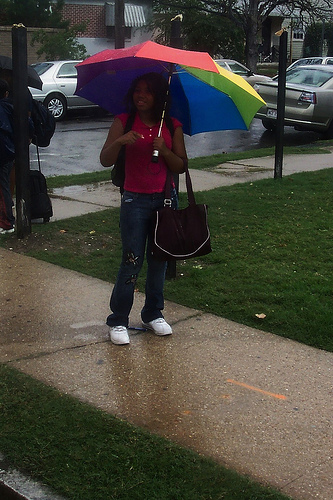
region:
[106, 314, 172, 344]
Girl wearing shoes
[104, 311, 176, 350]
Girl is wearing shoes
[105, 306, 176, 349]
Girl wearing white shoes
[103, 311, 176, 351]
Girl is wearing white shoes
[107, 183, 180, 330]
Girl wearing pants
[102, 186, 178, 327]
Girl is wearing pants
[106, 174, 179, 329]
Girl wearing blue pants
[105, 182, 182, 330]
Girl is wearing blue pants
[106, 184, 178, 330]
Girl wearing blue jeans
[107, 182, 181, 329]
Girl is wearing blue jeans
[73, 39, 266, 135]
a rainbow striped umbrella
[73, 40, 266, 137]
an open umbrella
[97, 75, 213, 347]
a young girl standing on sidewalk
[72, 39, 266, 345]
a young girl standing under umbrella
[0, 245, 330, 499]
a wet paved sidewalk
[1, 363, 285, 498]
a patch of green grass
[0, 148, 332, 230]
a paved wet sidewalk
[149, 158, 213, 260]
a large black bag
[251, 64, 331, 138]
a parked silver car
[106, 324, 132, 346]
a white shoe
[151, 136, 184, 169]
a hand holding a umbrella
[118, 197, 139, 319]
blue jeans worn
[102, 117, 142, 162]
the hand of a lady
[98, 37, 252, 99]
an umbrella over the head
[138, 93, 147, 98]
the nose of a lady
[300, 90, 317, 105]
the rear light of a car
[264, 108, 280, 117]
the number plate of a car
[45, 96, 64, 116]
the wheel of a car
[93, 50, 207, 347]
This is a lady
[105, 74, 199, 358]
This is a lady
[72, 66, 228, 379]
This is a lady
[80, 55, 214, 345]
This is a lady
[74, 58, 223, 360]
This is a lady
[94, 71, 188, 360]
This is a lady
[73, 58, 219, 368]
This is a lady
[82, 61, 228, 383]
This is a lady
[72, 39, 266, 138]
rainbow of color on an umbrella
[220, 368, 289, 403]
neon orange utility marker on sidewalk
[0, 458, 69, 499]
granite curb at road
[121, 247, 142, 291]
flower appliques on blue jeans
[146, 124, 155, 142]
two buttons on a henley collar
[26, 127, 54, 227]
black rolling back pack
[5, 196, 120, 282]
worn patch of lawn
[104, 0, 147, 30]
green and white striped awning over a window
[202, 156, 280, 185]
sidewalk section broken in two